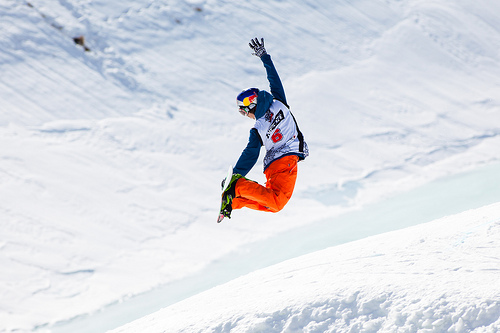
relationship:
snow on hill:
[0, 0, 498, 330] [30, 10, 166, 168]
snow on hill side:
[0, 0, 498, 330] [2, 0, 487, 196]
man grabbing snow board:
[207, 34, 310, 214] [212, 167, 235, 226]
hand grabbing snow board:
[210, 172, 238, 201] [213, 171, 250, 234]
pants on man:
[235, 154, 300, 212] [216, 32, 313, 225]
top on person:
[249, 94, 311, 172] [209, 35, 311, 225]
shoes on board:
[215, 171, 243, 212] [210, 171, 240, 225]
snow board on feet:
[216, 165, 235, 226] [226, 172, 241, 191]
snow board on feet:
[216, 165, 235, 226] [221, 195, 232, 215]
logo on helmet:
[241, 95, 260, 107] [236, 88, 263, 115]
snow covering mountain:
[0, 0, 498, 330] [1, 25, 497, 287]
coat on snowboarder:
[226, 53, 310, 180] [218, 33, 310, 221]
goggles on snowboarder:
[235, 106, 255, 119] [213, 30, 310, 229]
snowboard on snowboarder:
[217, 164, 239, 224] [218, 33, 310, 221]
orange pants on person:
[222, 154, 295, 211] [221, 28, 307, 226]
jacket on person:
[218, 48, 310, 216] [209, 35, 311, 225]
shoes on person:
[214, 171, 244, 222] [209, 35, 311, 225]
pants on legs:
[214, 140, 372, 257] [239, 164, 316, 216]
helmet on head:
[232, 88, 274, 120] [240, 88, 262, 118]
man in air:
[214, 34, 310, 223] [114, 51, 294, 203]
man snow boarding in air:
[207, 34, 310, 214] [104, 51, 246, 143]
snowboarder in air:
[197, 55, 313, 285] [136, 59, 344, 259]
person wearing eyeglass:
[215, 54, 314, 186] [231, 105, 263, 113]